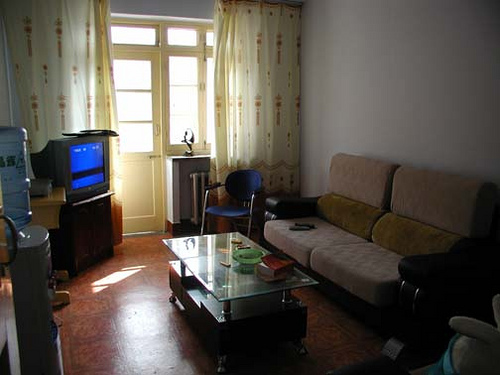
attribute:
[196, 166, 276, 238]
chair — small, blue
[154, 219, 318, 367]
table — glass, coffee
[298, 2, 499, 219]
wall — white, painted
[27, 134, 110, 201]
television — black, analog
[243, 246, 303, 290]
book — big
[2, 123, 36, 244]
water jug — big,  blue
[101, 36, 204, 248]
door — yellow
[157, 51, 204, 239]
door — beige, wooden, glass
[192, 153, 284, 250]
chair — blue 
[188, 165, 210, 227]
radiator — metal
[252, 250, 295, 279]
book — thick, red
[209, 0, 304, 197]
curtain — long, light yellow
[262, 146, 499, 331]
love seat — beige, lime green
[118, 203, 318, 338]
table — coffee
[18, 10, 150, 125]
curtain — long, door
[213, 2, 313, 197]
curtain — cream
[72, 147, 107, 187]
color —  blue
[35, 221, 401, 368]
flooring — shiny, wood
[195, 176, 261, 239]
arms — silver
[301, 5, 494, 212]
walls — bare, gray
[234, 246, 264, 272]
bowl — green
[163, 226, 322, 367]
table — coffee, glass topped